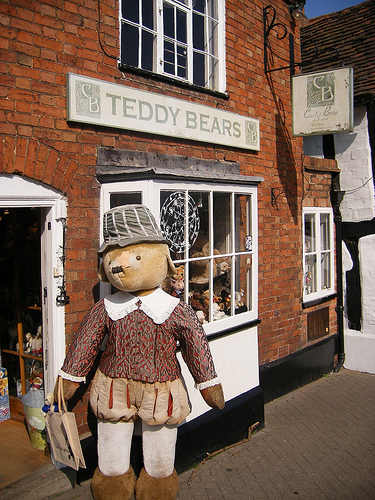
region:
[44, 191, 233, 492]
a very large teddy bear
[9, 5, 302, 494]
the front of the Teddy Bears shop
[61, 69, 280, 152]
the Teddy Bears sign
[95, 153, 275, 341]
the front window of a store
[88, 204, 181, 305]
a teddy bear wearing a hat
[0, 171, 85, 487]
the door of a shop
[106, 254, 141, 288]
the face of a Teddy bear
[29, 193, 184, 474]
a Teddy bear holding a bag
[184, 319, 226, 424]
the arm of a teddy bear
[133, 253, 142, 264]
the eye of a teddy bear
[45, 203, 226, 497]
A large stuffed teddy bear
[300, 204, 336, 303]
A white window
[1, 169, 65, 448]
A white door frame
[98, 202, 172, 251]
A grey hat on a teddy bear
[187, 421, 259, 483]
A brown stick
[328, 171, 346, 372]
A black drain pipe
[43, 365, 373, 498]
A brick sidewalk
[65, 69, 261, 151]
A teddy bear store sign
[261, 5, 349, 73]
A cast iron sign holder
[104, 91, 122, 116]
A light green letter T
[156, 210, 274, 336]
several stuffed teddy bears in a window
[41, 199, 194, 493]
a large stuffed teddy bear holding a bag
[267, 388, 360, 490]
a brick side walk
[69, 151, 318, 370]
a red brick building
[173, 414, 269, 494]
a tree branch on the sidewalk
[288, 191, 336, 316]
a white window on a building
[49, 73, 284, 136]
a sign on the front of a building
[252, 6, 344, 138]
a sign mounted to the front of a building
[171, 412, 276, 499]
a stick on the sidewalk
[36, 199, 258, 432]
bear with a hat on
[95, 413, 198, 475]
legs of the bear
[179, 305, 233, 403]
arm of the bear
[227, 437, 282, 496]
ground under the bear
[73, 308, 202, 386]
shirt on the bear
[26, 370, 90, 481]
bag in bear's arm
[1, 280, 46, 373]
items inside the building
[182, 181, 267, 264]
window of the place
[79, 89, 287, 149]
words above the window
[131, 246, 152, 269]
eye of the bear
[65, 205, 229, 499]
A human sized teddy bear on the street.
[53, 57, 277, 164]
A Teddy Bear store and gift shop.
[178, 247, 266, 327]
Lots of little teddy bears in the window.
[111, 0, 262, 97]
The building has a second floor.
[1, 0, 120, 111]
The building is made of red brick.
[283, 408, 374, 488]
There is a stone street in front of the store.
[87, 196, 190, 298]
This teddy bear is wearing a hat.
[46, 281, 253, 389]
The teddy bear is wearing a shirt.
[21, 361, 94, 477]
The teddy bear is going shopping at the gift store.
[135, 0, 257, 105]
There are beautiful old windows on this building.